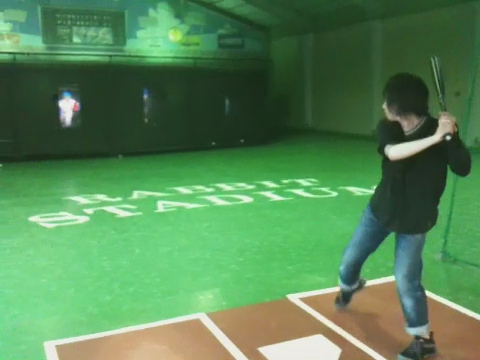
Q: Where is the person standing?
A: In the white box.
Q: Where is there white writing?
A: On the ground.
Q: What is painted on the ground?
A: Brown dirt.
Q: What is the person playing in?
A: An indoor batting cage.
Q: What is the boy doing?
A: Practicing.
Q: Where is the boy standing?
A: Batters box.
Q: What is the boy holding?
A: Bat.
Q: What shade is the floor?
A: Green.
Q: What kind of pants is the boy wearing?
A: Jeans.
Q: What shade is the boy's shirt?
A: Black.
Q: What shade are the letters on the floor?
A: White.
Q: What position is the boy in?
A: Standing.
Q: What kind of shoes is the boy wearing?
A: Tennis.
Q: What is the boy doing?
A: Playing baseball.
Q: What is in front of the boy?
A: A screen.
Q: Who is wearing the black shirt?
A: The boy.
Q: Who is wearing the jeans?
A: The boy.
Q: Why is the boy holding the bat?
A: To hit the ball.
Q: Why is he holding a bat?
A: To hit.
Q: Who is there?
A: Boy.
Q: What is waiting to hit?
A: Ball.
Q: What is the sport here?
A: Baseball.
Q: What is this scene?
A: Simulation.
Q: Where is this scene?
A: Baseball simulator field.